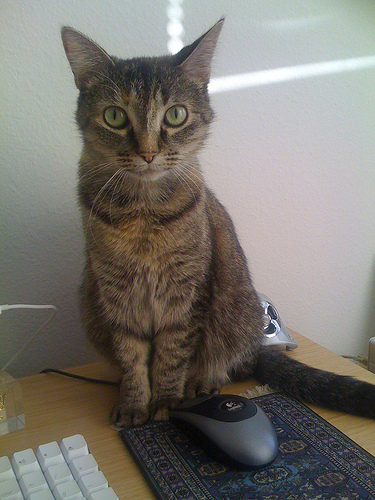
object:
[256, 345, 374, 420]
tail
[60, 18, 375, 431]
cat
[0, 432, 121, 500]
keyboard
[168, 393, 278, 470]
mouse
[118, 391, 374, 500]
mousepad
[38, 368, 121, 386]
cord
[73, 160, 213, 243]
whiskers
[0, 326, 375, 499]
desk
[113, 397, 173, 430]
paws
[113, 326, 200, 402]
legs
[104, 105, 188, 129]
eyes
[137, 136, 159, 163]
nose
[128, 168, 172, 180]
mouth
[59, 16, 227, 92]
ears